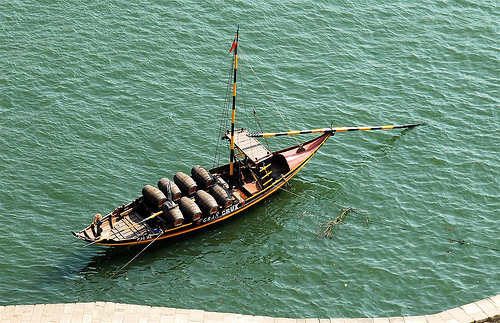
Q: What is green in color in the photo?
A: A large body of water.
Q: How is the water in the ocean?
A: It is so green.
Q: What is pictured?
A: A boat.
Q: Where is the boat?
A: In water.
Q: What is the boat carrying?
A: Barrels.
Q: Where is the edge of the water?
A: Bottom of the picture.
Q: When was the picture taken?
A: During day hours.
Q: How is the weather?
A: Clear.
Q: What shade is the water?
A: Green.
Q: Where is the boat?
A: Water.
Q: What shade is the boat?
A: Brown.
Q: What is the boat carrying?
A: Cargo.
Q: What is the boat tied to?
A: Wall.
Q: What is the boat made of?
A: Wood.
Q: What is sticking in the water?
A: Sail pole.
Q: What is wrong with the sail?
A: Broken.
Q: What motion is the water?
A: Calm.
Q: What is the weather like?
A: Sunny.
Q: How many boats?
A: One.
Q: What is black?
A: Inside the boat.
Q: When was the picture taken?
A: Daytime.